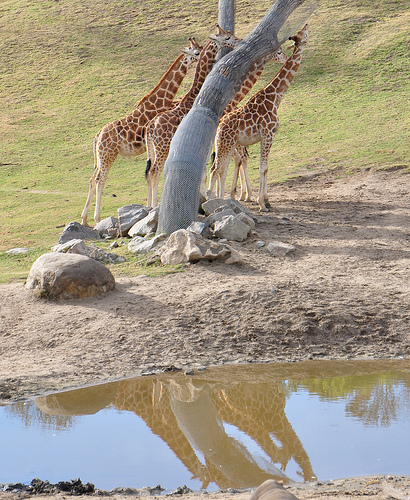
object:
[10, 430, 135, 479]
water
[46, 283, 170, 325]
shadows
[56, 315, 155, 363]
surface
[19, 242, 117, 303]
rock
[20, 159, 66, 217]
grass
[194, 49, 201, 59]
eye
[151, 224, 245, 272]
rocks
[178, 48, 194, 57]
ears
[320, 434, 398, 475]
water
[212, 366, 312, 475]
reflection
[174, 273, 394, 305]
beach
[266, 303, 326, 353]
footprints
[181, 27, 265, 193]
leaves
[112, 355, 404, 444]
hole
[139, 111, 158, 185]
tail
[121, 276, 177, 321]
sand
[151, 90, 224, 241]
tree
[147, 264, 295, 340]
hillside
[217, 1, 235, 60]
tree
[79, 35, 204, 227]
giraffe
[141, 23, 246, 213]
giraffe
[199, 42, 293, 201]
giraffe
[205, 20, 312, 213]
giraffe